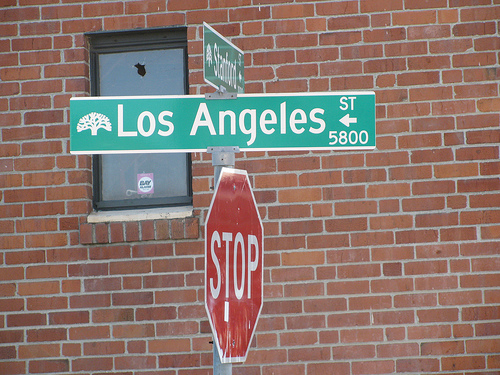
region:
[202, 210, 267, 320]
a stop sign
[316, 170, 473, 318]
the building is made out of bricks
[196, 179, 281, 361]
stop sign is red and white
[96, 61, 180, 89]
a window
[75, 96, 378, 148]
a street sign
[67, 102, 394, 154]
street sign is green and white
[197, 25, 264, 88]
a street sign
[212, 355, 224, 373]
a metal pole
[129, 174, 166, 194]
a sticker in the window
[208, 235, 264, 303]
white letters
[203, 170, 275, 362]
Red street stop sign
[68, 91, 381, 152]
Green Los Angeles Street sign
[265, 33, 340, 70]
Part of red brick building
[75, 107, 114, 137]
Decoration on green street sign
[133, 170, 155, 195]
Sign in building window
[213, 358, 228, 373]
Part of Red Stop sign pole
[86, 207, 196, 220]
Part of white window sill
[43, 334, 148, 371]
Part of red brick building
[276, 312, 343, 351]
Part of red brick building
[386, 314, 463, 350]
Pat of red brick building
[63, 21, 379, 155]
green and white street sign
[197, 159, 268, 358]
tilted view of a stop sign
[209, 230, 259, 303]
the word "stop" on a sign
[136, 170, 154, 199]
tag on the glass window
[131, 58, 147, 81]
hole in the glass window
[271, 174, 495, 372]
brick material on the wall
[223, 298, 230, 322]
white sticker on the stop sign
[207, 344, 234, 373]
metal post holding up the signs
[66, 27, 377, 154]
cross streets on the signs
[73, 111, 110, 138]
white tree on the sign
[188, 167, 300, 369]
Red stop sign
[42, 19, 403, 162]
Green street signs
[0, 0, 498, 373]
Red brick wall behind a street sign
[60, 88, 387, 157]
A green street sign with white letters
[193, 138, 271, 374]
Stop sign on a metal pole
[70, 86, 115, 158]
Tree stamped over green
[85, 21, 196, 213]
An opaque window behind a sign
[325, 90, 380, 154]
Building numbers under an arrow and the letters st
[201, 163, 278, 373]
Angled stop sign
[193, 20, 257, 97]
Angled street sign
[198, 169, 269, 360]
side view of a stop sign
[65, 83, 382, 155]
street name on a sign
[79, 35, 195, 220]
window on a brick building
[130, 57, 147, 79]
broken part of a window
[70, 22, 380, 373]
stop sign and street sign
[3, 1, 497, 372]
brick building in the background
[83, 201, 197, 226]
ledge in front of the window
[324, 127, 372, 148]
street number 5800 on the sign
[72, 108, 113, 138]
white tree symbol on the street sign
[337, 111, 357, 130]
white arrow symbol on the street sign